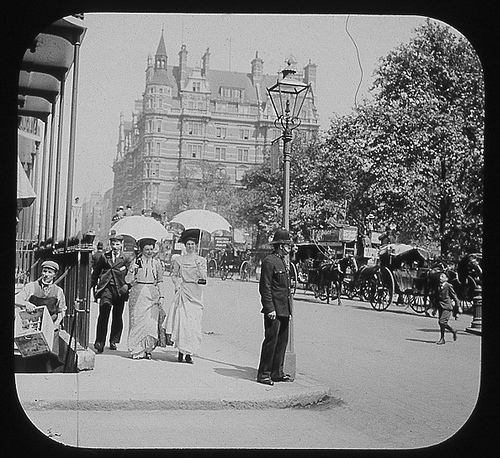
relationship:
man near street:
[255, 230, 296, 386] [210, 291, 483, 427]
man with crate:
[15, 260, 67, 373] [15, 306, 55, 358]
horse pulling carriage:
[318, 254, 357, 307] [290, 243, 315, 299]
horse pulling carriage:
[424, 255, 482, 322] [366, 242, 429, 313]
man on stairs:
[15, 260, 67, 373] [15, 248, 93, 374]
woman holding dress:
[170, 234, 206, 366] [174, 253, 205, 352]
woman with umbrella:
[125, 240, 163, 361] [110, 215, 173, 241]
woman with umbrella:
[170, 234, 206, 366] [168, 208, 231, 236]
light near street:
[268, 64, 311, 136] [210, 291, 483, 427]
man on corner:
[255, 230, 296, 386] [236, 367, 325, 405]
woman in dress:
[125, 240, 163, 361] [129, 257, 172, 356]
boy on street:
[436, 273, 464, 343] [210, 291, 483, 427]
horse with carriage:
[318, 254, 357, 307] [290, 243, 315, 299]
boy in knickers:
[436, 273, 464, 343] [436, 325, 459, 344]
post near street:
[282, 134, 291, 226] [210, 291, 483, 427]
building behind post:
[111, 21, 320, 209] [282, 134, 291, 226]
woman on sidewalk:
[125, 240, 163, 361] [5, 338, 322, 415]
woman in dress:
[125, 240, 163, 361] [174, 253, 205, 352]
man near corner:
[255, 230, 296, 386] [236, 367, 325, 405]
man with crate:
[255, 230, 296, 386] [15, 306, 55, 358]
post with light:
[282, 134, 291, 226] [268, 64, 311, 136]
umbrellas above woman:
[109, 208, 235, 243] [125, 240, 163, 361]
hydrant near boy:
[471, 285, 484, 331] [436, 273, 464, 343]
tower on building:
[142, 23, 170, 213] [111, 21, 320, 209]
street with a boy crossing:
[210, 291, 483, 427] [436, 273, 464, 343]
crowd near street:
[88, 208, 234, 368] [210, 291, 483, 427]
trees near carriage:
[170, 17, 487, 253] [290, 243, 315, 299]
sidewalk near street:
[5, 338, 322, 415] [210, 291, 483, 427]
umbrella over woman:
[110, 215, 173, 241] [125, 240, 163, 361]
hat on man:
[270, 228, 296, 244] [255, 230, 296, 386]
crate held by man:
[15, 306, 55, 358] [15, 260, 67, 373]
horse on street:
[318, 254, 357, 307] [210, 291, 483, 427]